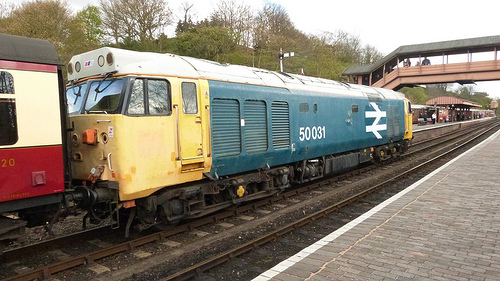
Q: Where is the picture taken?
A: A railway.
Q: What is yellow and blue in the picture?
A: A train.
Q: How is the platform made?
A: Of brick.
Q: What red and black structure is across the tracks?
A: A bridge.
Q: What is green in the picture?
A: Trees.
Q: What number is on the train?
A: 50031.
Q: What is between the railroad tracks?
A: Gravel.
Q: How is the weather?
A: Overcast.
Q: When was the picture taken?
A: Afternoon.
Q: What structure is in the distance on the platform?
A: A shelter.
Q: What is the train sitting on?
A: A track.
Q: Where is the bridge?
A: Over the track.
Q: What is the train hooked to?
A: Another car.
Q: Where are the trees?
A: Behind the train.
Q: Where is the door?
A: On front of train.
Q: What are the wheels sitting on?
A: The track.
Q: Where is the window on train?
A: On the front.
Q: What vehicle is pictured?
A: A train.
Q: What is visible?
A: The train's yellow door.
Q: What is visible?
A: The door's window.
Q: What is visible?
A: The train tracks.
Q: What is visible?
A: The train's side windows.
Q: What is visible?
A: The rusty tracks.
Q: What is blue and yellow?
A: The train is.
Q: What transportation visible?
A: Train.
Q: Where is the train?
A: On tracks.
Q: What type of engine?
A: Train.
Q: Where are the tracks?
A: Near station.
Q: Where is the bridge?
A: Over tracks.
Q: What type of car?
A: Train.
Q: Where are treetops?
A: Along tracks.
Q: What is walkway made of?
A: Bricks.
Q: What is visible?
A: Train.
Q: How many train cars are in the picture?
A: 2.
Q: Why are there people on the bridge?
A: Watching the train.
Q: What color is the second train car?
A: Blue and yellow.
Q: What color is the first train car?
A: Red and creme.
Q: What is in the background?
A: A bridge.